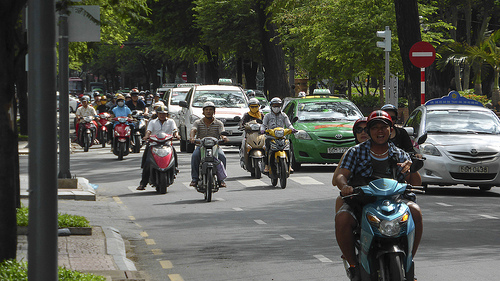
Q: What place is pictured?
A: It is a road.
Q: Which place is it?
A: It is a road.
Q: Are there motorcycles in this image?
A: Yes, there is a motorcycle.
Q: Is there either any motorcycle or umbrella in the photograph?
A: Yes, there is a motorcycle.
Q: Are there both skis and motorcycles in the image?
A: No, there is a motorcycle but no skis.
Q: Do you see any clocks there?
A: No, there are no clocks.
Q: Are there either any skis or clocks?
A: No, there are no clocks or skis.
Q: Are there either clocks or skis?
A: No, there are no clocks or skis.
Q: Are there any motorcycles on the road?
A: Yes, there is a motorcycle on the road.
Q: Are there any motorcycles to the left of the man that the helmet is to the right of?
A: Yes, there is a motorcycle to the left of the man.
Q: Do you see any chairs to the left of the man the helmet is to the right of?
A: No, there is a motorcycle to the left of the man.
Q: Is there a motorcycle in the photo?
A: Yes, there is a motorcycle.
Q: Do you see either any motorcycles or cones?
A: Yes, there is a motorcycle.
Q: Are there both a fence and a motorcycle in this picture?
A: No, there is a motorcycle but no fences.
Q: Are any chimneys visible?
A: No, there are no chimneys.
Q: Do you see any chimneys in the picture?
A: No, there are no chimneys.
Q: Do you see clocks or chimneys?
A: No, there are no chimneys or clocks.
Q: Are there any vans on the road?
A: No, there is a motorcycle on the road.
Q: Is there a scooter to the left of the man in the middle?
A: No, there is a motorcycle to the left of the man.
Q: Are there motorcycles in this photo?
A: Yes, there is a motorcycle.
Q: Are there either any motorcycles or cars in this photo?
A: Yes, there is a motorcycle.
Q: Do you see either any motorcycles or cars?
A: Yes, there is a motorcycle.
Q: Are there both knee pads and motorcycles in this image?
A: No, there is a motorcycle but no knee pads.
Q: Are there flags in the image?
A: No, there are no flags.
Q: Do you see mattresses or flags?
A: No, there are no flags or mattresses.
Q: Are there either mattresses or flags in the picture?
A: No, there are no flags or mattresses.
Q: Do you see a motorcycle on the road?
A: Yes, there is a motorcycle on the road.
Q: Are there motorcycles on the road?
A: Yes, there is a motorcycle on the road.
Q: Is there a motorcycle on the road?
A: Yes, there is a motorcycle on the road.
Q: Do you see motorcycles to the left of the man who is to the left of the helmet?
A: Yes, there is a motorcycle to the left of the man.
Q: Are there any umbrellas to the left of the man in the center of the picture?
A: No, there is a motorcycle to the left of the man.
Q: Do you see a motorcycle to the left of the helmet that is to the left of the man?
A: Yes, there is a motorcycle to the left of the helmet.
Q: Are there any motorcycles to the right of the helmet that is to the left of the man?
A: No, the motorcycle is to the left of the helmet.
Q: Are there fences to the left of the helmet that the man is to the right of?
A: No, there is a motorcycle to the left of the helmet.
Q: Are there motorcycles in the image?
A: Yes, there is a motorcycle.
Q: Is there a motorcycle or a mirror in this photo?
A: Yes, there is a motorcycle.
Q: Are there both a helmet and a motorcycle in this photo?
A: Yes, there are both a motorcycle and a helmet.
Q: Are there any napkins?
A: No, there are no napkins.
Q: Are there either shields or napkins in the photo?
A: No, there are no napkins or shields.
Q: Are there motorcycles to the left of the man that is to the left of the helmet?
A: Yes, there is a motorcycle to the left of the man.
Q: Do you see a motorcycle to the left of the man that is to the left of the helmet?
A: Yes, there is a motorcycle to the left of the man.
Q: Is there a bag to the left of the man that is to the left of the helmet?
A: No, there is a motorcycle to the left of the man.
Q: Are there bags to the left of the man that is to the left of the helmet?
A: No, there is a motorcycle to the left of the man.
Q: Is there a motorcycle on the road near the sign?
A: Yes, there is a motorcycle on the road.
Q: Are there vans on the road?
A: No, there is a motorcycle on the road.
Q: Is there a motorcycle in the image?
A: Yes, there is a motorcycle.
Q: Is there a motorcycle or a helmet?
A: Yes, there is a motorcycle.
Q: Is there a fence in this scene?
A: No, there are no fences.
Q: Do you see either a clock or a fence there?
A: No, there are no fences or clocks.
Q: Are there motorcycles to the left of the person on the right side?
A: Yes, there is a motorcycle to the left of the person.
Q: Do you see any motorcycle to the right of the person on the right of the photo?
A: No, the motorcycle is to the left of the person.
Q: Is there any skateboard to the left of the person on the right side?
A: No, there is a motorcycle to the left of the person.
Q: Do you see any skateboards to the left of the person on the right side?
A: No, there is a motorcycle to the left of the person.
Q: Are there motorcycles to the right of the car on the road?
A: No, the motorcycle is to the left of the car.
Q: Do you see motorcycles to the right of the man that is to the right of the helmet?
A: Yes, there is a motorcycle to the right of the man.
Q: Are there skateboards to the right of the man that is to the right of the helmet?
A: No, there is a motorcycle to the right of the man.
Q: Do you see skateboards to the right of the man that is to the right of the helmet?
A: No, there is a motorcycle to the right of the man.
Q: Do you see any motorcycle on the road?
A: Yes, there is a motorcycle on the road.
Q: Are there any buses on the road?
A: No, there is a motorcycle on the road.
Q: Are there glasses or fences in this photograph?
A: No, there are no fences or glasses.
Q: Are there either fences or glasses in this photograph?
A: No, there are no fences or glasses.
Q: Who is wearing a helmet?
A: The man is wearing a helmet.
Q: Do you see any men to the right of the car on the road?
A: No, the man is to the left of the car.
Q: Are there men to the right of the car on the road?
A: No, the man is to the left of the car.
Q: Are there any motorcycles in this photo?
A: Yes, there is a motorcycle.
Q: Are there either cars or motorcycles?
A: Yes, there is a motorcycle.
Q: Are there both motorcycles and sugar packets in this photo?
A: No, there is a motorcycle but no sugar packets.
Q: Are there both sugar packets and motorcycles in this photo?
A: No, there is a motorcycle but no sugar packets.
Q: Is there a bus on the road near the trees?
A: No, there is a motorcycle on the road.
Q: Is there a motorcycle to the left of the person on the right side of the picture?
A: Yes, there is a motorcycle to the left of the person.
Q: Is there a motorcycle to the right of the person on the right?
A: No, the motorcycle is to the left of the person.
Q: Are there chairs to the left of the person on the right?
A: No, there is a motorcycle to the left of the person.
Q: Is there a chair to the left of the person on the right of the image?
A: No, there is a motorcycle to the left of the person.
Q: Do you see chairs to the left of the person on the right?
A: No, there is a motorcycle to the left of the person.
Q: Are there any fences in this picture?
A: No, there are no fences.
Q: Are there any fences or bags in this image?
A: No, there are no fences or bags.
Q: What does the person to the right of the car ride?
A: The person rides a motorcycle.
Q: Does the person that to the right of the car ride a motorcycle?
A: Yes, the person rides a motorcycle.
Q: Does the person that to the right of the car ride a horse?
A: No, the person rides a motorcycle.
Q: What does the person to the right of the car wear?
A: The person wears a helmet.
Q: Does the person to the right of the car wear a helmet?
A: Yes, the person wears a helmet.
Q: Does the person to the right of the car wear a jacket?
A: No, the person wears a helmet.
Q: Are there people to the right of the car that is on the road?
A: Yes, there is a person to the right of the car.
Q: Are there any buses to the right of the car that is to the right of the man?
A: No, there is a person to the right of the car.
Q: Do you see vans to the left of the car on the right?
A: No, there is a person to the left of the car.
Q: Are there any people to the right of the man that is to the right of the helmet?
A: Yes, there is a person to the right of the man.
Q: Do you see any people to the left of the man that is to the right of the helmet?
A: No, the person is to the right of the man.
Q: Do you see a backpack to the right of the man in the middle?
A: No, there is a person to the right of the man.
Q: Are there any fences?
A: No, there are no fences.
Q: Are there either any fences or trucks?
A: No, there are no fences or trucks.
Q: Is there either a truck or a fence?
A: No, there are no fences or trucks.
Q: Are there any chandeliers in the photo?
A: No, there are no chandeliers.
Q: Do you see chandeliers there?
A: No, there are no chandeliers.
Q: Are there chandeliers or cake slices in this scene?
A: No, there are no chandeliers or cake slices.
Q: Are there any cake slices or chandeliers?
A: No, there are no chandeliers or cake slices.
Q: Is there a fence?
A: No, there are no fences.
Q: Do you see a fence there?
A: No, there are no fences.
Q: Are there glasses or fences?
A: No, there are no fences or glasses.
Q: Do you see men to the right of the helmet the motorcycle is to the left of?
A: Yes, there is a man to the right of the helmet.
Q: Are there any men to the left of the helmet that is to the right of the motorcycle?
A: No, the man is to the right of the helmet.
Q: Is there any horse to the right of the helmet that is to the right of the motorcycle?
A: No, there is a man to the right of the helmet.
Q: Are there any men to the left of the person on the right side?
A: Yes, there is a man to the left of the person.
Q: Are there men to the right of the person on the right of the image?
A: No, the man is to the left of the person.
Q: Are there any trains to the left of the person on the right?
A: No, there is a man to the left of the person.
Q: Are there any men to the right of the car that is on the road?
A: No, the man is to the left of the car.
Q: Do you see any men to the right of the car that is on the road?
A: No, the man is to the left of the car.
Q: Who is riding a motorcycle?
A: The man is riding a motorcycle.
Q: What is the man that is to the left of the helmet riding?
A: The man is riding a motorcycle.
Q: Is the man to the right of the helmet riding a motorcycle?
A: Yes, the man is riding a motorcycle.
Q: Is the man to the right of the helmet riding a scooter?
A: No, the man is riding a motorcycle.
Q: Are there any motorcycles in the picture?
A: Yes, there is a motorcycle.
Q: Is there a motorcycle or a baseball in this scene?
A: Yes, there is a motorcycle.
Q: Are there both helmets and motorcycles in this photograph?
A: Yes, there are both a motorcycle and a helmet.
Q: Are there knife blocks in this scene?
A: No, there are no knife blocks.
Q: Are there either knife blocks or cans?
A: No, there are no knife blocks or cans.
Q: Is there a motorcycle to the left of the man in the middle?
A: Yes, there is a motorcycle to the left of the man.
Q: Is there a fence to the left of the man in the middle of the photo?
A: No, there is a motorcycle to the left of the man.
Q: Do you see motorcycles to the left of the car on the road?
A: Yes, there is a motorcycle to the left of the car.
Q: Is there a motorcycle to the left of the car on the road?
A: Yes, there is a motorcycle to the left of the car.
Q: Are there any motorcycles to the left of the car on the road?
A: Yes, there is a motorcycle to the left of the car.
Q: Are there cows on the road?
A: No, there is a motorcycle on the road.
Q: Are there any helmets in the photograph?
A: Yes, there is a helmet.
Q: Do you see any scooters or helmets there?
A: Yes, there is a helmet.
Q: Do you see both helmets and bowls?
A: No, there is a helmet but no bowls.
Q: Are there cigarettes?
A: No, there are no cigarettes.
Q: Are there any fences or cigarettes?
A: No, there are no cigarettes or fences.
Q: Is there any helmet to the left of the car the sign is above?
A: Yes, there is a helmet to the left of the car.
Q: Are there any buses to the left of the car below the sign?
A: No, there is a helmet to the left of the car.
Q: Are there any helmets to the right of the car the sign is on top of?
A: Yes, there is a helmet to the right of the car.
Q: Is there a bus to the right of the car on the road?
A: No, there is a helmet to the right of the car.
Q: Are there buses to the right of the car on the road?
A: No, there is a helmet to the right of the car.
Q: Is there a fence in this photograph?
A: No, there are no fences.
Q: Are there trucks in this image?
A: No, there are no trucks.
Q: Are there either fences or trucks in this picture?
A: No, there are no trucks or fences.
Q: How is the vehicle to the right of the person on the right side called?
A: The vehicle is a car.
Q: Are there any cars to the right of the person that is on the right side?
A: Yes, there is a car to the right of the person.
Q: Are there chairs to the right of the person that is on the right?
A: No, there is a car to the right of the person.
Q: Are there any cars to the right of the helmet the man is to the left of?
A: Yes, there is a car to the right of the helmet.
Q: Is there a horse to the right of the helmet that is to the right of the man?
A: No, there is a car to the right of the helmet.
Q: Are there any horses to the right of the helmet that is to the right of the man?
A: No, there is a car to the right of the helmet.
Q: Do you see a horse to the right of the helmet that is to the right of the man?
A: No, there is a car to the right of the helmet.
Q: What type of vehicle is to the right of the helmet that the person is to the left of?
A: The vehicle is a car.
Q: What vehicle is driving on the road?
A: The vehicle is a car.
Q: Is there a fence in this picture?
A: No, there are no fences.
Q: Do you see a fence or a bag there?
A: No, there are no fences or bags.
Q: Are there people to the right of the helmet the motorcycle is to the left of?
A: Yes, there is a person to the right of the helmet.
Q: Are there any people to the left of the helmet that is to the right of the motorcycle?
A: No, the person is to the right of the helmet.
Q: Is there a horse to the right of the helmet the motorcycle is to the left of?
A: No, there is a person to the right of the helmet.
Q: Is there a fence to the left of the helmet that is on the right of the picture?
A: No, there is a person to the left of the helmet.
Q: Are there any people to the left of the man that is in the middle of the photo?
A: No, the person is to the right of the man.